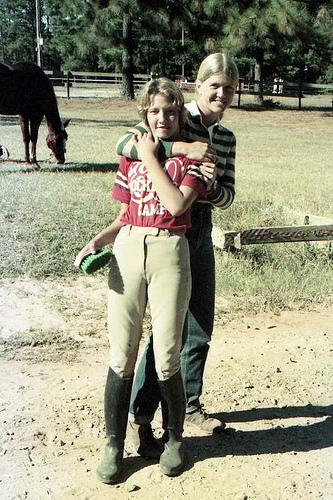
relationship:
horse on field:
[0, 59, 74, 169] [227, 109, 332, 214]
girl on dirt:
[118, 51, 236, 456] [2, 275, 331, 497]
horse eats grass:
[2, 52, 72, 167] [2, 98, 331, 303]